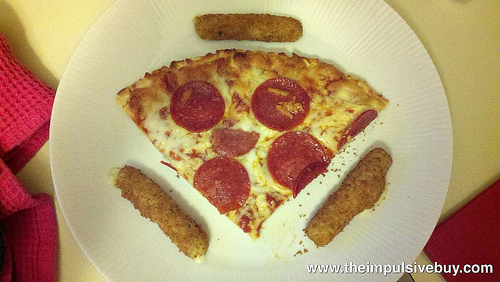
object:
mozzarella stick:
[301, 146, 392, 247]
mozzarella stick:
[109, 163, 211, 264]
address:
[303, 261, 492, 274]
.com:
[460, 261, 495, 274]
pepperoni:
[172, 79, 222, 133]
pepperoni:
[195, 156, 248, 211]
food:
[107, 13, 393, 266]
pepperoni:
[208, 125, 261, 158]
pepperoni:
[337, 109, 377, 150]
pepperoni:
[262, 128, 333, 197]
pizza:
[114, 47, 389, 237]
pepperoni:
[247, 75, 317, 133]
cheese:
[121, 48, 389, 241]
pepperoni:
[167, 79, 226, 133]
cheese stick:
[189, 11, 302, 44]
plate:
[51, 0, 460, 280]